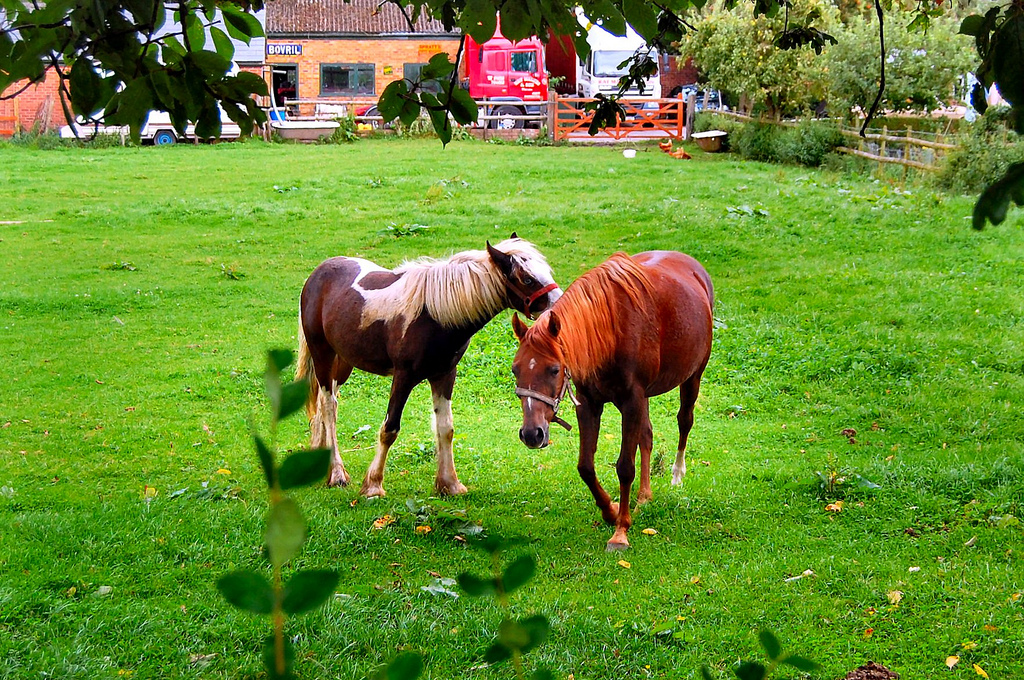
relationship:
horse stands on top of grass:
[511, 239, 720, 552] [4, 135, 1020, 679]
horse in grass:
[511, 239, 720, 552] [4, 135, 1020, 679]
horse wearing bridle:
[511, 239, 720, 552] [514, 383, 571, 431]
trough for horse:
[270, 117, 341, 146] [511, 239, 720, 552]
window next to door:
[315, 60, 380, 94] [271, 62, 302, 120]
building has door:
[263, 11, 472, 118] [271, 62, 302, 120]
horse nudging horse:
[283, 230, 564, 508] [511, 239, 720, 552]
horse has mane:
[283, 230, 564, 508] [383, 237, 544, 341]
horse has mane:
[511, 239, 720, 552] [520, 257, 671, 390]